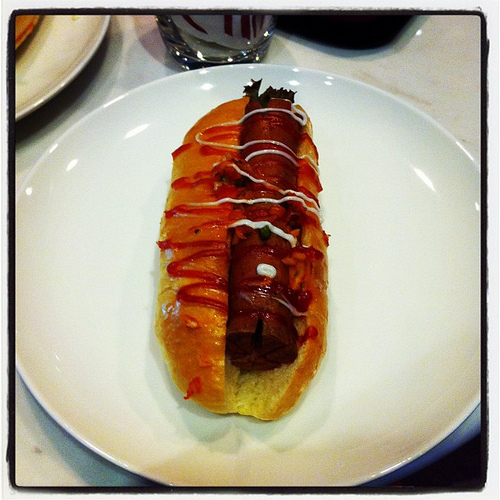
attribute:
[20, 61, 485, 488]
plate — white, portion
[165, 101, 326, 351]
sauce — white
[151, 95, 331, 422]
bun — brown, yellow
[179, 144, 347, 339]
toppings — red, white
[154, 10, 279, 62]
glass — clear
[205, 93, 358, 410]
hot dog — grilled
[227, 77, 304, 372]
hotdog — grilled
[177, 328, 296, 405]
bun — yellow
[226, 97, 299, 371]
hot dog — grilled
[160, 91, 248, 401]
bun — gold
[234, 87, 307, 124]
lettuce — portion, green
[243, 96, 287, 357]
dog — hot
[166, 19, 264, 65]
glass — clear, bottom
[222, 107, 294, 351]
dog — hot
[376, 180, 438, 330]
plate — white, large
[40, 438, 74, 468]
table — white